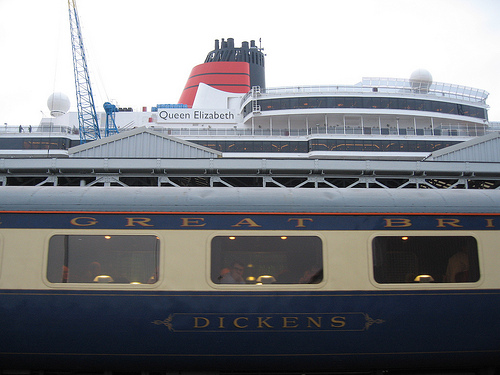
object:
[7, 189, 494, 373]
train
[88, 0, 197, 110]
sky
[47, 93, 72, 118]
white circle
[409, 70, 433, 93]
white circle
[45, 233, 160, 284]
window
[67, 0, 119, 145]
crane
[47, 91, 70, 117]
dome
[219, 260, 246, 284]
passenger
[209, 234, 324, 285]
window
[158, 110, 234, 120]
queen elizabeth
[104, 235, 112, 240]
light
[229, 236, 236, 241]
light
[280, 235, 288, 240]
light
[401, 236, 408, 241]
light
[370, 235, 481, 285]
windows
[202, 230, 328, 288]
windows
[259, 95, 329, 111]
windows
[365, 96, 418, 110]
windows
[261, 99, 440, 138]
windows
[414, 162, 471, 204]
ground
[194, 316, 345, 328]
word dickens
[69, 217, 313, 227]
word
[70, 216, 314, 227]
letters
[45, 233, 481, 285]
windows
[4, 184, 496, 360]
train car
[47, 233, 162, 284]
3 windoes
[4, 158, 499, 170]
stripe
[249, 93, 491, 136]
balcony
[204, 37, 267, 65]
stacks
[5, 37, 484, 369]
ship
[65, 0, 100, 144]
ladder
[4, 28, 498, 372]
boat